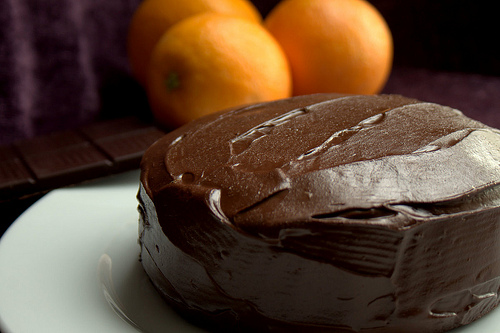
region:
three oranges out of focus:
[131, 0, 396, 96]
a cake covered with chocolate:
[136, 97, 497, 325]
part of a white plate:
[3, 180, 143, 329]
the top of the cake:
[154, 99, 496, 219]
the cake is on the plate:
[3, 97, 498, 331]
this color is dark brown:
[182, 128, 497, 215]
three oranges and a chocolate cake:
[122, 2, 497, 332]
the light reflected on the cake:
[340, 145, 496, 200]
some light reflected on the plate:
[96, 254, 133, 323]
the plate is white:
[3, 199, 123, 329]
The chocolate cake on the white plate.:
[137, 88, 499, 325]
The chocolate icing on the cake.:
[128, 95, 498, 325]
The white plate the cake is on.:
[9, 172, 496, 332]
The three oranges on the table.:
[115, 5, 396, 100]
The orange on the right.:
[273, 1, 395, 86]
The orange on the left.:
[157, 23, 279, 104]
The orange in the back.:
[126, 0, 262, 69]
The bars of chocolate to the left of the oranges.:
[11, 125, 159, 174]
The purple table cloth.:
[15, 9, 130, 107]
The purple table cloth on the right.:
[397, 58, 497, 125]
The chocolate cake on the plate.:
[134, 102, 498, 314]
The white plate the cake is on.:
[7, 191, 182, 331]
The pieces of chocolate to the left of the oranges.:
[4, 123, 151, 173]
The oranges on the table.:
[135, 2, 405, 95]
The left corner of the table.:
[5, 1, 148, 122]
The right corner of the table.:
[405, 25, 487, 126]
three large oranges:
[122, 0, 393, 117]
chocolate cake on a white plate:
[9, 75, 499, 332]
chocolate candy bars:
[5, 109, 164, 207]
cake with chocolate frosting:
[137, 84, 493, 324]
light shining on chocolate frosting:
[322, 114, 494, 196]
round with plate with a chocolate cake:
[7, 110, 497, 329]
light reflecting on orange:
[357, 8, 389, 60]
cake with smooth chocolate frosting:
[125, 108, 497, 316]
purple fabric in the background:
[11, 13, 113, 135]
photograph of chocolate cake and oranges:
[5, 7, 481, 321]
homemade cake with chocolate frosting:
[138, 91, 496, 331]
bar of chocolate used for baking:
[6, 116, 168, 192]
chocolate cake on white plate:
[3, 91, 496, 331]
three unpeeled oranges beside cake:
[126, 0, 393, 129]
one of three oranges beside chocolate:
[141, 11, 292, 131]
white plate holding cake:
[3, 168, 190, 331]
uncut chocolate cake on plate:
[134, 88, 498, 331]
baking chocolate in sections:
[6, 120, 167, 180]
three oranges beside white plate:
[126, 0, 396, 130]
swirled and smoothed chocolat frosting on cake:
[133, 92, 497, 332]